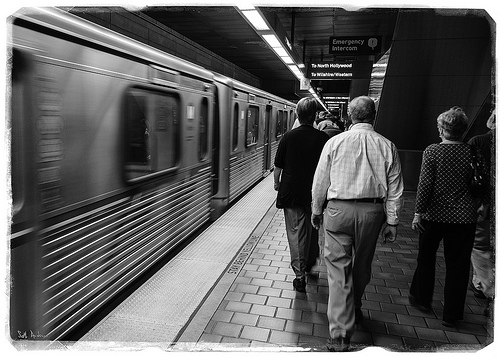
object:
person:
[274, 97, 331, 294]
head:
[295, 96, 320, 125]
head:
[347, 95, 377, 124]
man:
[310, 95, 404, 352]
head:
[437, 106, 469, 141]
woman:
[408, 106, 486, 327]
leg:
[283, 206, 308, 272]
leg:
[306, 208, 322, 265]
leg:
[324, 226, 354, 328]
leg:
[353, 233, 378, 305]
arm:
[274, 132, 295, 176]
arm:
[311, 134, 341, 213]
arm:
[386, 139, 405, 224]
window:
[122, 84, 182, 180]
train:
[8, 8, 297, 341]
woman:
[470, 108, 496, 300]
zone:
[76, 174, 500, 345]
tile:
[257, 315, 286, 331]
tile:
[251, 258, 272, 266]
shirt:
[273, 125, 331, 209]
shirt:
[310, 123, 404, 225]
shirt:
[415, 140, 489, 223]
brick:
[397, 313, 428, 327]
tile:
[213, 321, 243, 338]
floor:
[80, 208, 490, 341]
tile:
[414, 326, 450, 343]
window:
[200, 97, 209, 163]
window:
[232, 102, 239, 151]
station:
[10, 10, 487, 348]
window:
[247, 105, 260, 147]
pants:
[322, 200, 388, 339]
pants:
[409, 215, 477, 321]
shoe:
[408, 294, 434, 313]